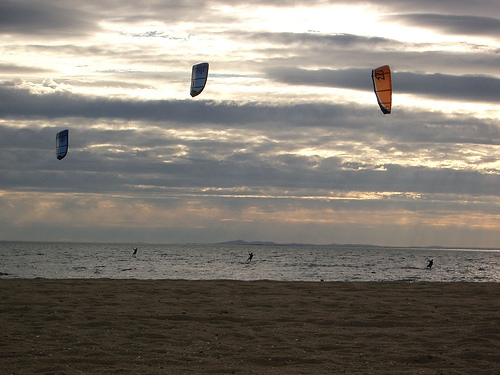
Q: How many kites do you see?
A: 3.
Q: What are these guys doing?
A: Water skiing.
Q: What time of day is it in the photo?
A: Dusk.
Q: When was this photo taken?
A: Early morning.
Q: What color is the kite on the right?
A: Orange.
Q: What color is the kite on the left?
A: Blue.